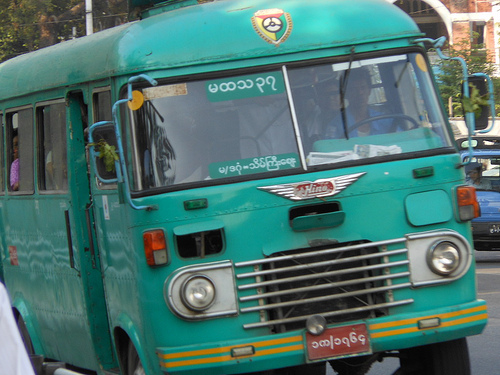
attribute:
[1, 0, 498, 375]
van — big, blue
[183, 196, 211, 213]
light — green 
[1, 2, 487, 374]
bus — green, small, blue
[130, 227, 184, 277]
blinker — orange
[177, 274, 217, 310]
light — green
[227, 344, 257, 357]
light — green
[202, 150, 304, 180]
sticker — foreign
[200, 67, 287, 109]
sticker — foreign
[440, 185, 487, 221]
light — green 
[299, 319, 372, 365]
license plate — red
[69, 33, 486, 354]
bus — green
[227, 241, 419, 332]
grill — metal